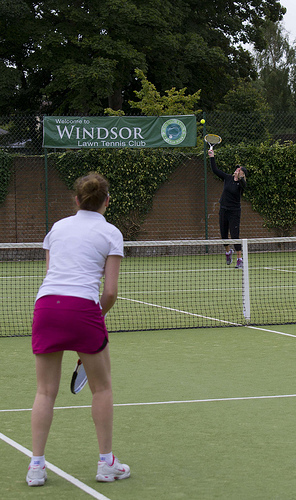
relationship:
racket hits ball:
[199, 131, 226, 162] [199, 117, 209, 123]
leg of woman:
[68, 344, 124, 465] [27, 175, 128, 500]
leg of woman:
[21, 346, 64, 468] [27, 175, 128, 500]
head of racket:
[202, 131, 225, 144] [199, 131, 226, 162]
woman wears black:
[192, 131, 250, 268] [207, 152, 246, 262]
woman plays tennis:
[27, 175, 128, 500] [9, 120, 296, 500]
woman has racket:
[192, 131, 250, 268] [199, 131, 226, 162]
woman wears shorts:
[27, 175, 128, 500] [29, 292, 108, 360]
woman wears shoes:
[27, 175, 128, 500] [23, 447, 134, 493]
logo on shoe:
[112, 470, 135, 480] [86, 458, 136, 487]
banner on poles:
[36, 115, 203, 154] [40, 148, 217, 257]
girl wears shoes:
[27, 175, 128, 500] [23, 447, 134, 493]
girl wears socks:
[27, 175, 128, 500] [29, 453, 116, 466]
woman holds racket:
[27, 175, 128, 500] [62, 350, 93, 398]